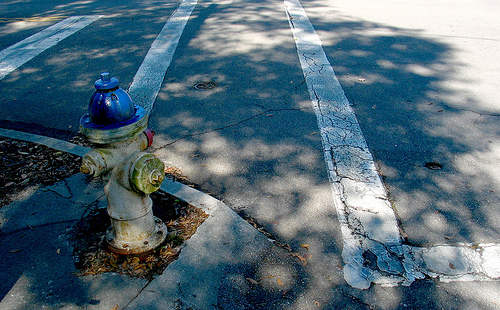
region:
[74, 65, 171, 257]
a fire hydrant is by the street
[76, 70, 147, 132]
the hyhdrant's cap is blue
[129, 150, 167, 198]
a green plug is on the hydrant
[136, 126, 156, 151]
a red plug is on the side of the hydrant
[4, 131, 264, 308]
leaves are scattered around the hydrant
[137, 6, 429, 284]
white lines are in the street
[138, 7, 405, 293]
the white lines are for pedestrians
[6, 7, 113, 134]
a thick white line is for traffic to stop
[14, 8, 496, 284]
the street is shaded by trees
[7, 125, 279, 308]
the curb is next to the street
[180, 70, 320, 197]
road has cracks in it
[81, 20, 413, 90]
painted lines on the road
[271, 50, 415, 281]
lines are the color white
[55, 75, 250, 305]
fire hydrant on the road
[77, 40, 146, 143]
top of hydrant is blue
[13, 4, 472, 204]
shadow on the road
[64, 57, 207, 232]
fire hydrant is old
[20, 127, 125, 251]
rocks on side of road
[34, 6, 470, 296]
road for cars to drive on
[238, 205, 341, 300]
weeds on the road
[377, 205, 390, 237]
the line is white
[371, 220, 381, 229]
the line is white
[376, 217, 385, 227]
the line is white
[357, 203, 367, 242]
the line is white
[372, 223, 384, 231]
the line is white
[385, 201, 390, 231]
the line is white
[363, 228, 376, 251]
the line is white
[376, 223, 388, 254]
the line is white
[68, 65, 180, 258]
fire hydrant on side of road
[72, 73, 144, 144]
top of fire hydrant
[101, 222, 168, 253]
base of fire hydrant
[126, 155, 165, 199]
side bolt of hydrant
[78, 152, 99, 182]
side bolt of hydrant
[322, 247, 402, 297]
corner of white line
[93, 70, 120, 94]
blue bolt on fire hydrant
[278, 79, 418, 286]
white line of parking slot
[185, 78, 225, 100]
metal spot in parking lot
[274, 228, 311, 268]
leaves on asphalt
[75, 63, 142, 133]
painted blue fire hydrant top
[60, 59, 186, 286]
a fire hydrant on the street corner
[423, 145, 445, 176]
a hole in the asphalt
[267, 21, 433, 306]
white stripe in the pavement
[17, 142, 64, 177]
bark on the curb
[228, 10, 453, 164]
shadows of trees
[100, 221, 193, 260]
bolts on the fire hydrant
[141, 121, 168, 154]
red piece of the hydrant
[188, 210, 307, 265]
cement curb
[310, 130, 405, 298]
cracked paint